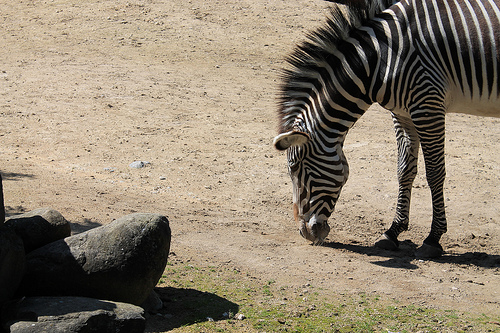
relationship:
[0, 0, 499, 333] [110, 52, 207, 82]
brown dirt on ground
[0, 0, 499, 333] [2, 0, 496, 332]
brown dirt on ground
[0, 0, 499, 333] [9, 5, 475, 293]
brown dirt on ground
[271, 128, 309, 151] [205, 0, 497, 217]
ear of zebra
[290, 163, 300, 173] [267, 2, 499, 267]
eye of zebra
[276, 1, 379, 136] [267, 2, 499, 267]
hair on zebra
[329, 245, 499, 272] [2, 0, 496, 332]
shadow on ground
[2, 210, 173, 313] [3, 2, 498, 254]
boulder on ground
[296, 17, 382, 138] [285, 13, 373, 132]
wide stripes on neck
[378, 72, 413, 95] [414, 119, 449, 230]
stripes on leg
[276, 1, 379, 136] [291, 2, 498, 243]
hair of zebra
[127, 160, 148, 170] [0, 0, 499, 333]
rock on brown dirt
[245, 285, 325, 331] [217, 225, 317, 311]
grass on ground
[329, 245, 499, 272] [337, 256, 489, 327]
shadow on ground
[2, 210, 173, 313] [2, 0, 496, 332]
boulder on ground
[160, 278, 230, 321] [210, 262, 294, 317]
shadow on ground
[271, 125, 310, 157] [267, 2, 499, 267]
ear on zebra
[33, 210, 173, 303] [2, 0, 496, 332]
boulder on ground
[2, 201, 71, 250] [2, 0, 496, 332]
boulder on ground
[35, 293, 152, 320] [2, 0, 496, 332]
boulder on ground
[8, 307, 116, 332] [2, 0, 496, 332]
boulder on ground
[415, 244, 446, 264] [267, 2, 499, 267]
hoove of zebra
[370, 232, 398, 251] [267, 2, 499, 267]
hoove of zebra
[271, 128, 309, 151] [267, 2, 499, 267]
ear of zebra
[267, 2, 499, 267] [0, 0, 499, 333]
zebra standing in brown dirt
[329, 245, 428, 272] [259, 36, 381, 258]
shadow from zebra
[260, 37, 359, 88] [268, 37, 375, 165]
hair sticking up on neck